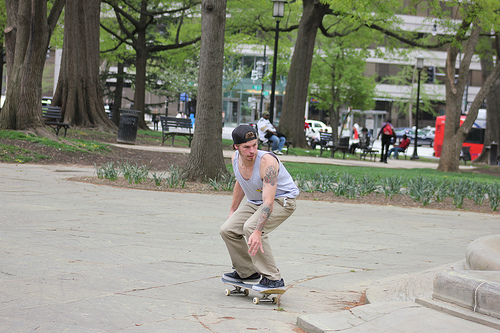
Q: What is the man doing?
A: Skateboarding.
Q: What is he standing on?
A: Skateboard.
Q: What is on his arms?
A: Tattoos.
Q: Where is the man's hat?
A: Head.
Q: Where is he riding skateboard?
A: Park.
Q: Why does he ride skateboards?
A: Entertainment.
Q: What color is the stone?
A: Grey.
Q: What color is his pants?
A: Brown.